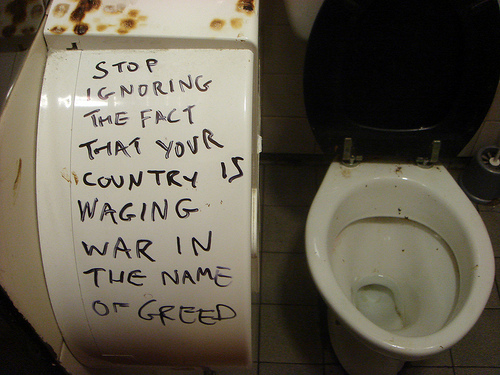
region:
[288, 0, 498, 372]
Toilet in a public restroom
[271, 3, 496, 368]
Toilet that needs cleaning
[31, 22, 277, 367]
Toilet tissue dispenser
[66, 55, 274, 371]
Graffiti on a toilet tissue dispenser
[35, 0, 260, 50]
Rust marks on metal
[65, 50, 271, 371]
Graffiti written in black ink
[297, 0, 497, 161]
Lid of a toilet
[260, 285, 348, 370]
Tiles on a restroom floor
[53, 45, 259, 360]
Graffiti written about politics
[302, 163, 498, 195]
Stains on a toilet bowl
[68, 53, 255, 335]
A message written in black marker on a white surface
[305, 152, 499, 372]
A dirty open toilet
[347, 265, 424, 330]
Water in a toilet bowl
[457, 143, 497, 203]
A toilet cleaner in a silver case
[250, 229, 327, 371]
A gray tile floor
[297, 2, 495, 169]
The black lid of a toilet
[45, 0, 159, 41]
Brown stains and rust on a metal surface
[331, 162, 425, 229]
The dirty edge of a toilet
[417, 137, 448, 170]
The metal hinge of a toilet lid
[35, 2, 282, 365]
A toilet paper holder with a message on it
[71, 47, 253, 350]
grafitti in a public toilet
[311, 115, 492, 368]
this toilet is filthy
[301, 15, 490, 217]
the seat & lid are black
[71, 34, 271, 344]
this is where the toilet paper is stored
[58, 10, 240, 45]
rust spots on metal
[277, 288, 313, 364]
the floor is made of tile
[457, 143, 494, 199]
a toilet brush is in the corner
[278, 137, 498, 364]
it looks like someone needs to use it on the toilet!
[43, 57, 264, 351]
the grafitti is true.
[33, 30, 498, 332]
this whole photo is disgusting.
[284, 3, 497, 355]
the dirty toilet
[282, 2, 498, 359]
the disgusting toilet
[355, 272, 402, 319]
the toilet water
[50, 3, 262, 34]
the rust on the toilet paper dispenser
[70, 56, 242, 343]
the writing on the toilet paper dispenser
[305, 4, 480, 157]
the dark toilet seat cover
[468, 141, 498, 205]
the toilet bowl cleaner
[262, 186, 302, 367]
the tiled ground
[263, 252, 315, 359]
the shadow from the toilet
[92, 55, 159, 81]
the written word STOP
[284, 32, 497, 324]
a dirty bathroom toilet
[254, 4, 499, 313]
a nasty bathroom toilet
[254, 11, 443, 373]
a black and white toilet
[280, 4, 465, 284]
a bathroom toilet that is nasty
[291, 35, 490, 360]
a bathroom toilet that is dirty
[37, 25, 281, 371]
writing on the paper towel holder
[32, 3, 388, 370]
rusted paper towl holder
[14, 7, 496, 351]
a very dirty bathroom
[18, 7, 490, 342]
a very nasty bathroom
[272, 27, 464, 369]
a toilet with the seat up